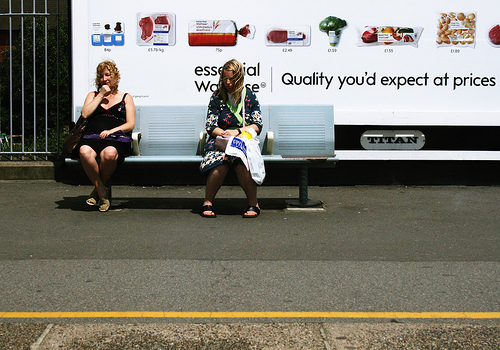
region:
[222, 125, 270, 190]
White plastic bags on the woman's lap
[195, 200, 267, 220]
Pair of black sandals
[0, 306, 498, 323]
Long orange yellow line on the pavement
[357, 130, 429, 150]
Black and white "Titan" sign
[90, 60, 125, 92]
Short curly blonde hair on a woman's head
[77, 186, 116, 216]
Tan and green sandals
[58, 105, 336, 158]
Light blue and gray bench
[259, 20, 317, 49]
Picture of a package of meat on a sign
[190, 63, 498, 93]
White sign with black writing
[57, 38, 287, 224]
Two women in the foreground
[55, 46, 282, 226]
Two women are sitting down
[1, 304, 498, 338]
A yellow line in the concrete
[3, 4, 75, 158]
A fence in the background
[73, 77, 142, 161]
Woman is wearing a dark colored dress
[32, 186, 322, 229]
Bench is casting a shadow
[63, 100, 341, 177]
The bench is light blue in color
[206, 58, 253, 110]
Woman has long hair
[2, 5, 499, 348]
Photo was taken outdoors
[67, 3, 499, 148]
A ad poster is in the background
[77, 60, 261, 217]
Two women sitting on a bench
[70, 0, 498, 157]
A big board of advertisement behind the women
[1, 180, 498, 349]
A railway platform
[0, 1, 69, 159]
A fence of vertical metal rods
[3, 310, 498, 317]
A yellow marking line on the platform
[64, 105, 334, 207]
The bench the women are sitting on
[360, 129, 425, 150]
An advertisement of 'TITAN'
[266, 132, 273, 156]
One of the handrests of the bench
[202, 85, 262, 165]
Colorful printed dress of a woman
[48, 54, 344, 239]
Two women sitting on a public bench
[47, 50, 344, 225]
Two women sitting on a public bench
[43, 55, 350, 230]
Two women sitting on a public bench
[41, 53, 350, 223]
Two women sitting on a public bench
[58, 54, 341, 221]
Two women sitting on a public bench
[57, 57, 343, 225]
Two women sitting on a public bench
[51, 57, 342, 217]
Two women sitting on a public bench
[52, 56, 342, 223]
Two women sitting on a public bench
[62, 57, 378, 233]
two woman on a bench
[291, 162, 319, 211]
leg of a bench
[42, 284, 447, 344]
yellow painted line on road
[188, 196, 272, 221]
sandals on woman's feet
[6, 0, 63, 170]
fence behind the women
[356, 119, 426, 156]
name on a vehicle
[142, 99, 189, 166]
bench where women sit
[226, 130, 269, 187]
bag in woman's hand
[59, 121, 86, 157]
purse of a woman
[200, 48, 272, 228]
this lady is waiting for the bus to take her to housekeeping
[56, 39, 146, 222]
this lady just wants to get home to rest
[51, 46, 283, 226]
these ladies are strangers and do not feel like communicating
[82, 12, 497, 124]
this billboard is advertising groceries at an affordable price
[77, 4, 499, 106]
this billboard is praising the quality and prices of their products